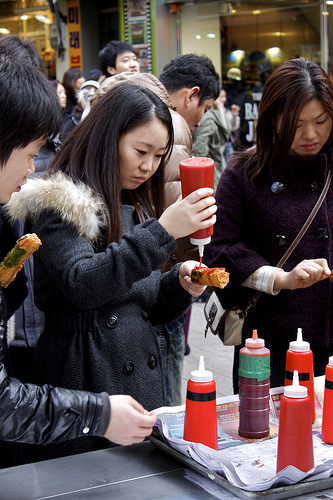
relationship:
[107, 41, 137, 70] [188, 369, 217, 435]
man reaching for bottle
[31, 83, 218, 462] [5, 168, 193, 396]
woman wearing coat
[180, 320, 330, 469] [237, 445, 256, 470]
sauces are on newspaper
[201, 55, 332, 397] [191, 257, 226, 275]
woman putting ketchup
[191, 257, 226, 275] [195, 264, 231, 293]
ketchup on food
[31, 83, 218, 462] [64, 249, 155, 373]
woman wearing coat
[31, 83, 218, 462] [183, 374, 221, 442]
woman using ketchup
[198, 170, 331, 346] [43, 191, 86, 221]
purse on shoulder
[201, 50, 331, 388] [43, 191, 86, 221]
woman has shoulder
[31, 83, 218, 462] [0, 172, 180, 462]
woman wearing coat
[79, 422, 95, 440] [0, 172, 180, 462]
buttons are on coat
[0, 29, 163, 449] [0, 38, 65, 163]
boy has hair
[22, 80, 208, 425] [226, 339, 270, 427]
woman using bottle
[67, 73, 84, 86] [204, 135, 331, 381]
woman wearing coat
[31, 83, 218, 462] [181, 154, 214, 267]
woman uses ketchup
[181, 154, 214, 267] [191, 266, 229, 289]
ketchup on a hotdog